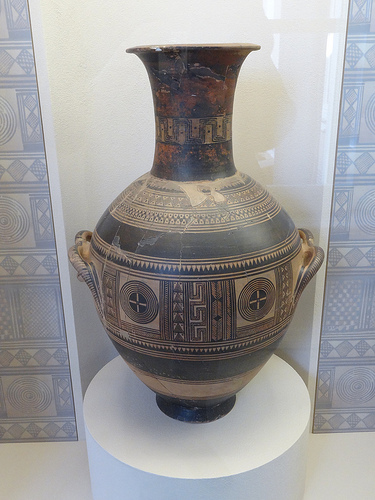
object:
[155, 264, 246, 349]
design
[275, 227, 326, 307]
handle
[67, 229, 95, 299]
handle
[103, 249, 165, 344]
design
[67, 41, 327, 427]
artifact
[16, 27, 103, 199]
museum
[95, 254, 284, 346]
patterns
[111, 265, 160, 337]
patterns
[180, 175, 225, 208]
spots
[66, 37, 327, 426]
pot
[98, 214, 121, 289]
crack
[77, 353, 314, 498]
pedestal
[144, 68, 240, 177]
neck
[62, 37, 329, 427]
pottery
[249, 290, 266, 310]
cross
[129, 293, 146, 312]
cross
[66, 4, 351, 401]
insert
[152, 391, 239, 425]
base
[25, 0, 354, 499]
display case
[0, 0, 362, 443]
wall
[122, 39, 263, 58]
opening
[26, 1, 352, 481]
glass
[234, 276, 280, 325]
design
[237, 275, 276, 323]
circle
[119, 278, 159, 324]
circle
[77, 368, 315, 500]
stand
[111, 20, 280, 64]
rim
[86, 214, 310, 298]
stripe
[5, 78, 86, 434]
pattern